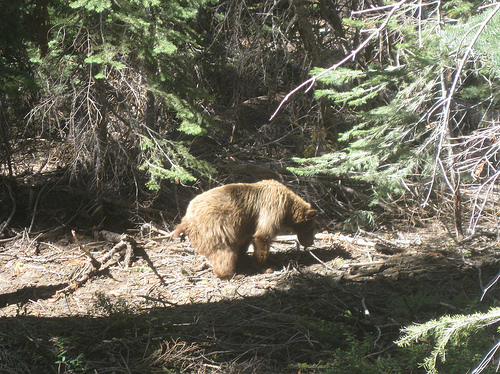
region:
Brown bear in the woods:
[171, 157, 315, 267]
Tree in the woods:
[57, 43, 205, 215]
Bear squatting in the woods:
[176, 182, 331, 278]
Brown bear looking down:
[181, 164, 345, 278]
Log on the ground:
[61, 222, 151, 297]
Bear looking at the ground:
[290, 195, 335, 242]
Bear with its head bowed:
[280, 186, 325, 258]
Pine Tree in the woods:
[294, 26, 468, 210]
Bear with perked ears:
[288, 202, 321, 237]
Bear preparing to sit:
[183, 195, 320, 276]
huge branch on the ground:
[82, 231, 154, 279]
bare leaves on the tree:
[63, 111, 129, 154]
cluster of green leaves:
[293, 56, 366, 120]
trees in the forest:
[179, 17, 433, 143]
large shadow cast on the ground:
[120, 285, 367, 340]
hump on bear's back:
[197, 176, 273, 196]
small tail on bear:
[149, 216, 239, 250]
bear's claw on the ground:
[250, 249, 282, 271]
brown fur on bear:
[188, 186, 270, 238]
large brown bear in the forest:
[134, 157, 329, 271]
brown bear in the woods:
[174, 178, 316, 278]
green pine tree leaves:
[3, 2, 498, 182]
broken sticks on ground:
[38, 218, 140, 298]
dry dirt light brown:
[0, 194, 497, 314]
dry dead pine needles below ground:
[0, 306, 499, 373]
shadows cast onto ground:
[3, 248, 498, 371]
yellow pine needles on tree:
[393, 299, 498, 370]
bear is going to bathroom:
[158, 178, 325, 288]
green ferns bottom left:
[11, 330, 90, 372]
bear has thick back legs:
[188, 198, 240, 277]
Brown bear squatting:
[166, 181, 318, 281]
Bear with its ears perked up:
[287, 197, 325, 238]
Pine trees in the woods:
[319, 50, 454, 224]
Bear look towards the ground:
[151, 175, 327, 265]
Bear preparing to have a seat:
[175, 186, 360, 281]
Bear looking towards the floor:
[264, 181, 343, 261]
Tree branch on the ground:
[61, 222, 147, 297]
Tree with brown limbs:
[116, 65, 243, 186]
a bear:
[160, 207, 323, 332]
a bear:
[146, 84, 308, 351]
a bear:
[132, 60, 249, 245]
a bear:
[206, 175, 332, 371]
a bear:
[194, 100, 414, 369]